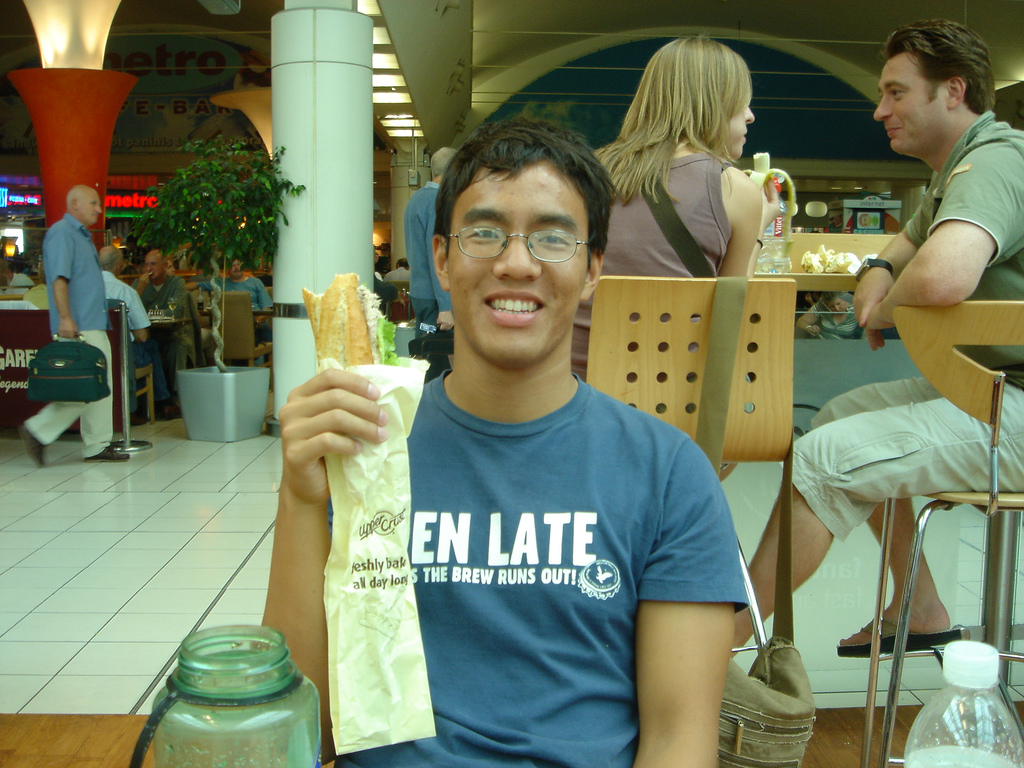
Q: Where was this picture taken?
A: A food court.